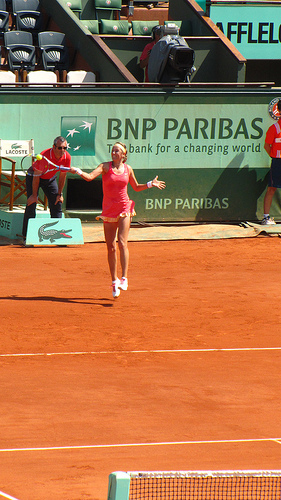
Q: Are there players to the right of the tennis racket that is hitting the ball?
A: Yes, there is a player to the right of the racket.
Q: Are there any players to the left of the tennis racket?
A: No, the player is to the right of the tennis racket.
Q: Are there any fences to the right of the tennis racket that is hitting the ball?
A: No, there is a player to the right of the tennis racket.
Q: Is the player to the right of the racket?
A: Yes, the player is to the right of the racket.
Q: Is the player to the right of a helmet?
A: No, the player is to the right of the racket.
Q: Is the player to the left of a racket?
A: No, the player is to the right of a racket.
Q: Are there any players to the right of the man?
A: Yes, there is a player to the right of the man.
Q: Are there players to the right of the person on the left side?
A: Yes, there is a player to the right of the man.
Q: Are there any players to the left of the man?
A: No, the player is to the right of the man.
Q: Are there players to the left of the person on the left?
A: No, the player is to the right of the man.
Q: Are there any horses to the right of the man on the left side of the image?
A: No, there is a player to the right of the man.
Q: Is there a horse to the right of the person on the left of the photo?
A: No, there is a player to the right of the man.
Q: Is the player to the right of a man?
A: Yes, the player is to the right of a man.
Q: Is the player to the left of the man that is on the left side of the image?
A: No, the player is to the right of the man.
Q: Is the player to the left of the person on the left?
A: No, the player is to the right of the man.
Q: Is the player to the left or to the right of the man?
A: The player is to the right of the man.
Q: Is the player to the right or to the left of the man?
A: The player is to the right of the man.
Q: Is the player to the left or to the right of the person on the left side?
A: The player is to the right of the man.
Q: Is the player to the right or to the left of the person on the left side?
A: The player is to the right of the man.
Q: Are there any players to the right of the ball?
A: Yes, there is a player to the right of the ball.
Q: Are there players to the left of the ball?
A: No, the player is to the right of the ball.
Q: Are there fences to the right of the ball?
A: No, there is a player to the right of the ball.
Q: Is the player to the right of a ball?
A: Yes, the player is to the right of a ball.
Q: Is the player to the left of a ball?
A: No, the player is to the right of a ball.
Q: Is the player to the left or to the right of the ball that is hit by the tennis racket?
A: The player is to the right of the ball.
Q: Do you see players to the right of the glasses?
A: Yes, there is a player to the right of the glasses.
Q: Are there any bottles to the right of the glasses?
A: No, there is a player to the right of the glasses.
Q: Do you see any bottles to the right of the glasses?
A: No, there is a player to the right of the glasses.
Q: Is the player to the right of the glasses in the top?
A: Yes, the player is to the right of the glasses.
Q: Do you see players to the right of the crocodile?
A: Yes, there is a player to the right of the crocodile.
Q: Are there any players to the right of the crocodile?
A: Yes, there is a player to the right of the crocodile.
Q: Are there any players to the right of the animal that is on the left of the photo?
A: Yes, there is a player to the right of the crocodile.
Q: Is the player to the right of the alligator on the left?
A: Yes, the player is to the right of the alligator.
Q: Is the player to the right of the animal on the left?
A: Yes, the player is to the right of the alligator.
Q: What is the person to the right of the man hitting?
A: The player is hitting the ball.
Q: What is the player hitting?
A: The player is hitting the ball.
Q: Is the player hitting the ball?
A: Yes, the player is hitting the ball.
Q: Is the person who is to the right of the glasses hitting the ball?
A: Yes, the player is hitting the ball.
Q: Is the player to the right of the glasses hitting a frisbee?
A: No, the player is hitting the ball.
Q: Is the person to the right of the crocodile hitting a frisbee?
A: No, the player is hitting the ball.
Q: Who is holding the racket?
A: The player is holding the racket.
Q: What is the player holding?
A: The player is holding the racket.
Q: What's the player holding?
A: The player is holding the racket.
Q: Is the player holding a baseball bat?
A: No, the player is holding the racket.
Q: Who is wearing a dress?
A: The player is wearing a dress.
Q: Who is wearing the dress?
A: The player is wearing a dress.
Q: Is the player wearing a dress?
A: Yes, the player is wearing a dress.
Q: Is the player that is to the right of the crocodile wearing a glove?
A: No, the player is wearing a dress.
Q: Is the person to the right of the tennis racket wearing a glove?
A: No, the player is wearing a dress.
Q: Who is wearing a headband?
A: The player is wearing a headband.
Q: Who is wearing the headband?
A: The player is wearing a headband.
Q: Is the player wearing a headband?
A: Yes, the player is wearing a headband.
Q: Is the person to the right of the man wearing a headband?
A: Yes, the player is wearing a headband.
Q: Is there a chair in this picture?
A: Yes, there is a chair.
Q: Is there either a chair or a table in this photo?
A: Yes, there is a chair.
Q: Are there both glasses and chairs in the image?
A: Yes, there are both a chair and glasses.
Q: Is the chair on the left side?
A: Yes, the chair is on the left of the image.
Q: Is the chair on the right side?
A: No, the chair is on the left of the image.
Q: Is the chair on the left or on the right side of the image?
A: The chair is on the left of the image.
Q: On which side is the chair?
A: The chair is on the left of the image.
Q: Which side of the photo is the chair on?
A: The chair is on the left of the image.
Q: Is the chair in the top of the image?
A: Yes, the chair is in the top of the image.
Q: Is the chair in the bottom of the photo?
A: No, the chair is in the top of the image.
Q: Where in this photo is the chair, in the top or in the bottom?
A: The chair is in the top of the image.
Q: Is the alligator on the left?
A: Yes, the alligator is on the left of the image.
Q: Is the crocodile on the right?
A: No, the crocodile is on the left of the image.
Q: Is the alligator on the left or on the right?
A: The alligator is on the left of the image.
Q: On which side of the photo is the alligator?
A: The alligator is on the left of the image.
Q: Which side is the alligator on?
A: The alligator is on the left of the image.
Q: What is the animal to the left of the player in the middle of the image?
A: The animal is an alligator.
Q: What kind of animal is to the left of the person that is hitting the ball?
A: The animal is an alligator.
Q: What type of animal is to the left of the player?
A: The animal is an alligator.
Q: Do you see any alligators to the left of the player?
A: Yes, there is an alligator to the left of the player.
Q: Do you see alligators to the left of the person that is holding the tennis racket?
A: Yes, there is an alligator to the left of the player.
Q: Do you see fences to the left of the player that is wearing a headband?
A: No, there is an alligator to the left of the player.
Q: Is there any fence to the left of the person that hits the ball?
A: No, there is an alligator to the left of the player.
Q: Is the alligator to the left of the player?
A: Yes, the alligator is to the left of the player.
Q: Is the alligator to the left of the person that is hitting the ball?
A: Yes, the alligator is to the left of the player.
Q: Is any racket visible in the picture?
A: Yes, there is a racket.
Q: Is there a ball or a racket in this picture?
A: Yes, there is a racket.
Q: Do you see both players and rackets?
A: Yes, there are both a racket and a player.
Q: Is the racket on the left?
A: Yes, the racket is on the left of the image.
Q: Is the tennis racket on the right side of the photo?
A: No, the tennis racket is on the left of the image.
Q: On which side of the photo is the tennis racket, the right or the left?
A: The tennis racket is on the left of the image.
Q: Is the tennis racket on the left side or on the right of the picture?
A: The tennis racket is on the left of the image.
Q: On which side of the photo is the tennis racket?
A: The tennis racket is on the left of the image.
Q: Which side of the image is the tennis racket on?
A: The tennis racket is on the left of the image.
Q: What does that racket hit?
A: The racket hits the ball.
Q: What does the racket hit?
A: The racket hits the ball.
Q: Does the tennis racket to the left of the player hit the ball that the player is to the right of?
A: Yes, the tennis racket hits the ball.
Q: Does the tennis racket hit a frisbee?
A: No, the tennis racket hits the ball.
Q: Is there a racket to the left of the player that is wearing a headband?
A: Yes, there is a racket to the left of the player.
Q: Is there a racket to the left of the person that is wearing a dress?
A: Yes, there is a racket to the left of the player.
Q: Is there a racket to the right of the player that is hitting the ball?
A: No, the racket is to the left of the player.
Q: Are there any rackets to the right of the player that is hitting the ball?
A: No, the racket is to the left of the player.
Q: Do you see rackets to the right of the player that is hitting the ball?
A: No, the racket is to the left of the player.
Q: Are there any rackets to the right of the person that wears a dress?
A: No, the racket is to the left of the player.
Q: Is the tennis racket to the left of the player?
A: Yes, the tennis racket is to the left of the player.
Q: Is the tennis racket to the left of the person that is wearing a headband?
A: Yes, the tennis racket is to the left of the player.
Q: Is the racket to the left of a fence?
A: No, the racket is to the left of the player.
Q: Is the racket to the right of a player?
A: No, the racket is to the left of a player.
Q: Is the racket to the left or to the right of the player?
A: The racket is to the left of the player.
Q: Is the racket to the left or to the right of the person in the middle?
A: The racket is to the left of the player.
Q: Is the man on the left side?
A: Yes, the man is on the left of the image.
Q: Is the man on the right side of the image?
A: No, the man is on the left of the image.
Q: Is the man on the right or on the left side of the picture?
A: The man is on the left of the image.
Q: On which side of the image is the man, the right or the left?
A: The man is on the left of the image.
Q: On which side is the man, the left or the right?
A: The man is on the left of the image.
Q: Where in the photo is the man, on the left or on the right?
A: The man is on the left of the image.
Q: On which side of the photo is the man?
A: The man is on the left of the image.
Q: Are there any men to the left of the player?
A: Yes, there is a man to the left of the player.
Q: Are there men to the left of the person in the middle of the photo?
A: Yes, there is a man to the left of the player.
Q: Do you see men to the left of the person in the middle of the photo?
A: Yes, there is a man to the left of the player.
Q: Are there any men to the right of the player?
A: No, the man is to the left of the player.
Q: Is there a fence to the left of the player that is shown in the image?
A: No, there is a man to the left of the player.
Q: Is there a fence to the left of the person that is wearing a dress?
A: No, there is a man to the left of the player.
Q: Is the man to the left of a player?
A: Yes, the man is to the left of a player.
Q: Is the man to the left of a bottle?
A: No, the man is to the left of a player.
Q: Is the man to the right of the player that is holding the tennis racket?
A: No, the man is to the left of the player.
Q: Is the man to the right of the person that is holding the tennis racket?
A: No, the man is to the left of the player.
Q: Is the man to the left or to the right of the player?
A: The man is to the left of the player.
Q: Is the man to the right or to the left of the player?
A: The man is to the left of the player.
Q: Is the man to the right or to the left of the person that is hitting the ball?
A: The man is to the left of the player.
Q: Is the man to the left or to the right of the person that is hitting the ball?
A: The man is to the left of the player.